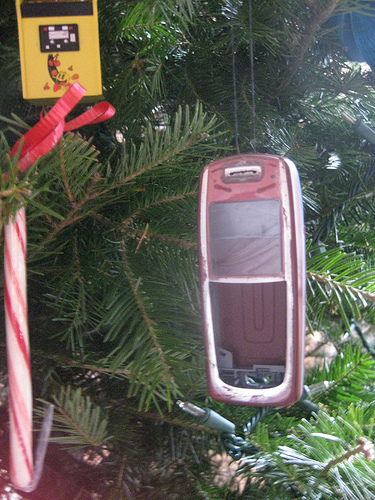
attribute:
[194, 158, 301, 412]
phone — red, broken, burgundy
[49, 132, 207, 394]
tree — green, evergreen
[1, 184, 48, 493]
candy — white, red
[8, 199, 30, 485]
cane — red, white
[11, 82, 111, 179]
ribbon — red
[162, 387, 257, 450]
light — clear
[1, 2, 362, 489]
scene — christmastime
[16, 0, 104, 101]
object — pac-man, yellow, black, rectangle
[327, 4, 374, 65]
ornament — blue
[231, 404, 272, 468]
cord — twisted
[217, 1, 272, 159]
strands — tied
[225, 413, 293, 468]
wires — green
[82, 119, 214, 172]
limb — green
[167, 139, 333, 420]
toy — maroon, rectangle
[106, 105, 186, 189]
leaflets — green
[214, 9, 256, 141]
rope — green